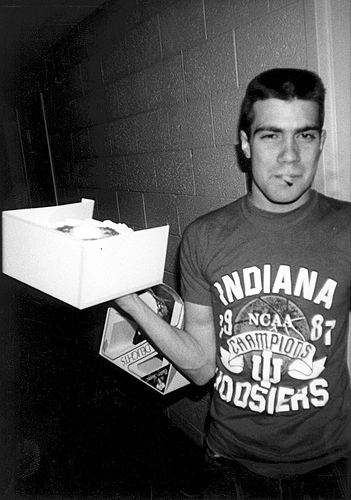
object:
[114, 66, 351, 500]
man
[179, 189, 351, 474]
shirt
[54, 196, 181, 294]
flap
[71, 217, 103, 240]
light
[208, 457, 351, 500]
pants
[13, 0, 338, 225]
wall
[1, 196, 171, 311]
box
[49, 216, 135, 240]
cake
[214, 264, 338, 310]
letters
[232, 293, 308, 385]
basketball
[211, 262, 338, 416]
fabric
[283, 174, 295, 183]
cigarette